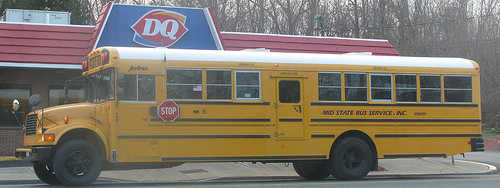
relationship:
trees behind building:
[1, 2, 500, 123] [1, 3, 402, 155]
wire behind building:
[222, 13, 499, 46] [1, 3, 402, 155]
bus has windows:
[15, 47, 487, 186] [85, 71, 473, 107]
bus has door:
[15, 47, 487, 186] [275, 76, 306, 142]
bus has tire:
[15, 47, 487, 186] [54, 141, 106, 187]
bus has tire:
[15, 47, 487, 186] [330, 135, 377, 180]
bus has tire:
[15, 47, 487, 186] [33, 161, 63, 186]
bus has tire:
[15, 47, 487, 186] [294, 160, 332, 178]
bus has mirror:
[15, 47, 487, 186] [29, 95, 42, 108]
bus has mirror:
[15, 47, 487, 186] [10, 100, 22, 112]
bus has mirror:
[15, 47, 487, 186] [62, 77, 71, 104]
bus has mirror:
[15, 47, 487, 186] [106, 68, 119, 104]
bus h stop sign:
[15, 47, 487, 186] [158, 99, 181, 124]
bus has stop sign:
[15, 47, 487, 186] [158, 99, 181, 124]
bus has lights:
[15, 47, 487, 186] [46, 54, 482, 145]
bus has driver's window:
[15, 47, 487, 186] [116, 72, 159, 104]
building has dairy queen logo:
[1, 3, 402, 155] [131, 6, 192, 48]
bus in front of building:
[15, 47, 487, 186] [1, 3, 402, 155]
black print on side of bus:
[321, 109, 428, 117] [15, 47, 487, 186]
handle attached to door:
[293, 103, 301, 113] [275, 76, 306, 142]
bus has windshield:
[15, 47, 487, 186] [84, 68, 115, 104]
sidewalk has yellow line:
[3, 154, 497, 179] [1, 156, 495, 179]